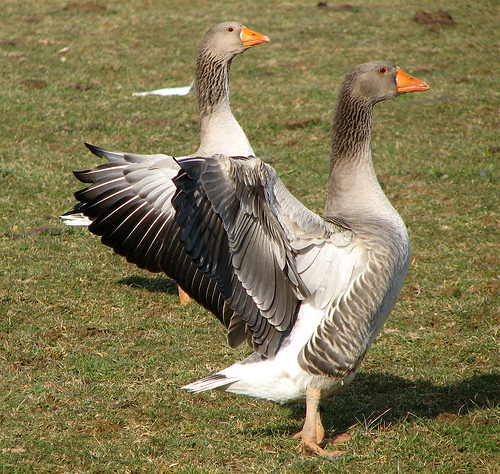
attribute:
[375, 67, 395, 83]
eye — orange, black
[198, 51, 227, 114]
neck — black, grey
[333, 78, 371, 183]
neck — tall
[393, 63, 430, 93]
beak — orange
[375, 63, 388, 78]
eye — orange, round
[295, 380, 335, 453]
leg — light colored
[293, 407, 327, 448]
leg — light colored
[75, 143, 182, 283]
wing — black tipped, extended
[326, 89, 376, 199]
neck — gray, black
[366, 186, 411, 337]
breast — white, gray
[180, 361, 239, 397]
tail feathers — light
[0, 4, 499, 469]
lawn — grassy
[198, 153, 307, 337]
wing — outstretched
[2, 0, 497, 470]
grass — green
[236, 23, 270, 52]
beak — orange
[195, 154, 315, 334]
wing — black tipped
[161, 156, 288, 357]
wing — outstretched, black tipped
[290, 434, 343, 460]
foot — white, orange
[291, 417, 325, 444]
foot — white, orange